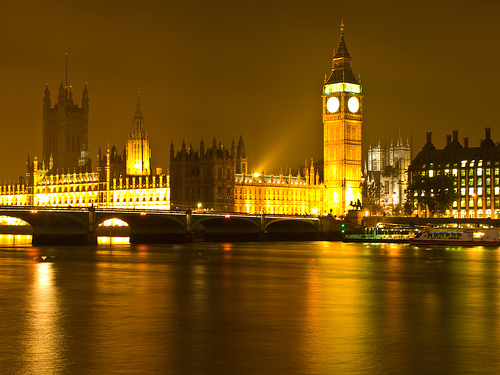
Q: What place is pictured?
A: It is a river.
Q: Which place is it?
A: It is a river.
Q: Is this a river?
A: Yes, it is a river.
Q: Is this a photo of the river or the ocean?
A: It is showing the river.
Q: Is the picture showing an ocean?
A: No, the picture is showing a river.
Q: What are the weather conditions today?
A: It is foggy.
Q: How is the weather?
A: It is foggy.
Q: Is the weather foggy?
A: Yes, it is foggy.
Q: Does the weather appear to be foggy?
A: Yes, it is foggy.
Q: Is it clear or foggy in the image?
A: It is foggy.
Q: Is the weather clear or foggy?
A: It is foggy.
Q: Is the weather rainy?
A: No, it is foggy.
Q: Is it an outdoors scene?
A: Yes, it is outdoors.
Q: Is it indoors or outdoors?
A: It is outdoors.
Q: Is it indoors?
A: No, it is outdoors.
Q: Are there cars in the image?
A: No, there are no cars.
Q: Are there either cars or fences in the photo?
A: No, there are no cars or fences.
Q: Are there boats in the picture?
A: Yes, there is a boat.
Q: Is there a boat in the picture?
A: Yes, there is a boat.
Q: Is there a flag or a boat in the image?
A: Yes, there is a boat.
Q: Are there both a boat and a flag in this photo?
A: No, there is a boat but no flags.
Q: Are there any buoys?
A: No, there are no buoys.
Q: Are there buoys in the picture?
A: No, there are no buoys.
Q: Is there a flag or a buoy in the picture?
A: No, there are no buoys or flags.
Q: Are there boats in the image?
A: Yes, there is a boat.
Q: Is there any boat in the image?
A: Yes, there is a boat.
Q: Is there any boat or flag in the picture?
A: Yes, there is a boat.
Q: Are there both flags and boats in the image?
A: No, there is a boat but no flags.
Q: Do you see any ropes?
A: No, there are no ropes.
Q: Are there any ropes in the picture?
A: No, there are no ropes.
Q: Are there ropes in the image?
A: No, there are no ropes.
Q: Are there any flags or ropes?
A: No, there are no ropes or flags.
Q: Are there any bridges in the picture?
A: Yes, there is a bridge.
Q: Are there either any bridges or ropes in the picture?
A: Yes, there is a bridge.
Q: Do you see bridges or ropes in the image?
A: Yes, there is a bridge.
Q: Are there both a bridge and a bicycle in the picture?
A: No, there is a bridge but no bicycles.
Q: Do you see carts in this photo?
A: No, there are no carts.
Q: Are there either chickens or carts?
A: No, there are no carts or chickens.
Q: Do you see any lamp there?
A: No, there are no lamps.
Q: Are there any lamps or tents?
A: No, there are no lamps or tents.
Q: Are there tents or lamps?
A: No, there are no lamps or tents.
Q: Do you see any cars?
A: No, there are no cars.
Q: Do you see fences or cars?
A: No, there are no cars or fences.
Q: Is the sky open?
A: Yes, the sky is open.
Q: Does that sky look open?
A: Yes, the sky is open.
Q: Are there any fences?
A: No, there are no fences.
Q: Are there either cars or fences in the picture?
A: No, there are no fences or cars.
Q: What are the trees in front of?
A: The trees are in front of the building.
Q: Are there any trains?
A: No, there are no trains.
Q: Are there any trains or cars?
A: No, there are no trains or cars.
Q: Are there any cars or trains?
A: No, there are no trains or cars.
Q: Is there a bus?
A: No, there are no buses.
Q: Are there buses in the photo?
A: No, there are no buses.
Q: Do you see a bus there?
A: No, there are no buses.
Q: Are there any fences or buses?
A: No, there are no buses or fences.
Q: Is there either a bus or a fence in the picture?
A: No, there are no buses or fences.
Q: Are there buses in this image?
A: No, there are no buses.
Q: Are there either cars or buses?
A: No, there are no buses or cars.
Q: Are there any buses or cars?
A: No, there are no buses or cars.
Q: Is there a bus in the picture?
A: No, there are no buses.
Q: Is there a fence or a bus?
A: No, there are no buses or fences.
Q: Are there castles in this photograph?
A: Yes, there is a castle.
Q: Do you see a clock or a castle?
A: Yes, there is a castle.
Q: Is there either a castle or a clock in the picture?
A: Yes, there is a castle.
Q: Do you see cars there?
A: No, there are no cars.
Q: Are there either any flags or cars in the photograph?
A: No, there are no cars or flags.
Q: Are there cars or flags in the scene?
A: No, there are no cars or flags.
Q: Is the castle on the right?
A: Yes, the castle is on the right of the image.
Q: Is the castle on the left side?
A: No, the castle is on the right of the image.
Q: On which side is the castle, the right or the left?
A: The castle is on the right of the image.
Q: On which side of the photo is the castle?
A: The castle is on the right of the image.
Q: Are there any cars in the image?
A: No, there are no cars.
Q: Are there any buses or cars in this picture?
A: No, there are no cars or buses.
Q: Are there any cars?
A: No, there are no cars.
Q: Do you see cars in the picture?
A: No, there are no cars.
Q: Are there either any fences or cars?
A: No, there are no cars or fences.